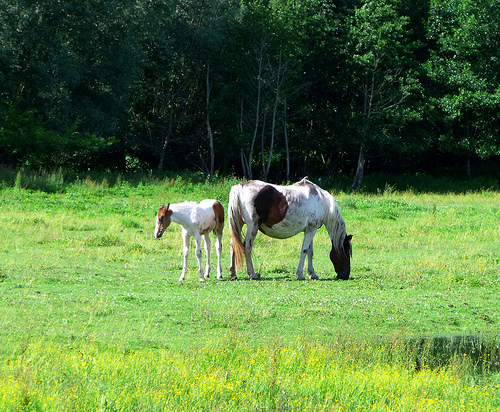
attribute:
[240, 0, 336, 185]
tree — tall 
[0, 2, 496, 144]
leaves — green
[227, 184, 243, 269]
tail — long flowing horse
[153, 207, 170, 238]
head — brown 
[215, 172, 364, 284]
horse — white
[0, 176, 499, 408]
grass — green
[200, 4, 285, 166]
tree — tall 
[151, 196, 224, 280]
baby horse — is white, is brown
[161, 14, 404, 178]
tree — tall 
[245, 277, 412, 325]
reflection — light